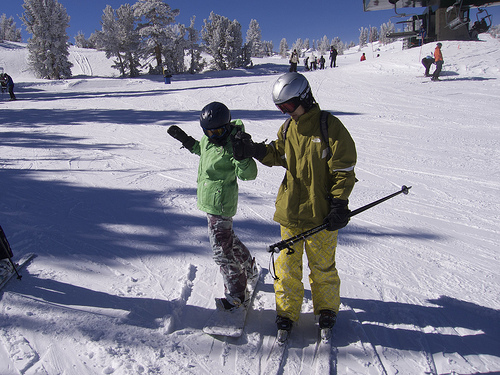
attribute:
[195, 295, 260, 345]
snowboard — snow covered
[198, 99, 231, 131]
helmet — black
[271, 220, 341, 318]
pants — snowpants, yellow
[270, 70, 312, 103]
helmet — silver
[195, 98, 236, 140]
helmet — green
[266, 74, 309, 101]
helmet — silver, protective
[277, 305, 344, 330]
boots — black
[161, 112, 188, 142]
mitten — black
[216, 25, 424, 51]
trees — distant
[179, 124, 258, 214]
greenjacket — green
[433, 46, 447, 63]
jacket — orange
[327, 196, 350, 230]
glove — black, winter glove, for snow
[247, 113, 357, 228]
coat — olive green